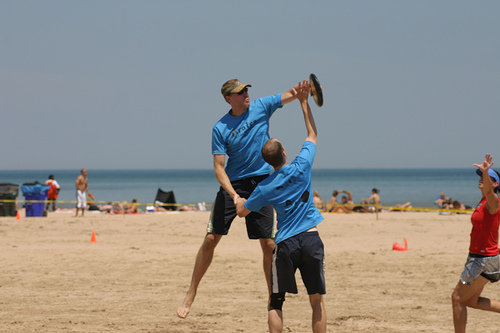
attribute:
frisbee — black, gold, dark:
[308, 74, 323, 108]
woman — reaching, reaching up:
[451, 153, 500, 331]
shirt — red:
[468, 196, 499, 256]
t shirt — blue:
[212, 93, 284, 181]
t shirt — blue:
[244, 139, 324, 243]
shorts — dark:
[207, 175, 278, 239]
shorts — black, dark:
[270, 231, 326, 296]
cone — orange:
[392, 242, 408, 252]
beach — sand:
[1, 208, 499, 331]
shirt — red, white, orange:
[45, 179, 61, 199]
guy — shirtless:
[76, 169, 93, 215]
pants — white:
[76, 189, 88, 210]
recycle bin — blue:
[20, 181, 53, 219]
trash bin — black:
[1, 181, 22, 219]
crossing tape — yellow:
[0, 197, 477, 216]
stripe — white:
[271, 243, 282, 294]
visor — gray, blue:
[476, 167, 499, 181]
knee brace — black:
[268, 291, 287, 313]